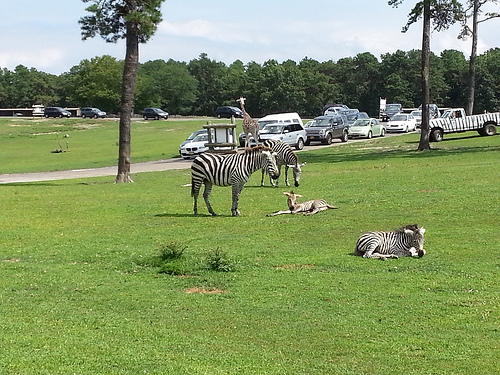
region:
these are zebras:
[51, 21, 336, 291]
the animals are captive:
[88, 113, 490, 360]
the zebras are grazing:
[170, 134, 377, 234]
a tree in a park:
[75, 0, 166, 184]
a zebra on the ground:
[352, 218, 427, 269]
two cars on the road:
[37, 101, 111, 121]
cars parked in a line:
[178, 98, 412, 156]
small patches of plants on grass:
[132, 231, 246, 289]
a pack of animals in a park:
[182, 135, 433, 270]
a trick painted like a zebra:
[427, 103, 498, 145]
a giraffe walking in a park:
[235, 87, 259, 149]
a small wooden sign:
[202, 115, 240, 153]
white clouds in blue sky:
[177, 1, 207, 36]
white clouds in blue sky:
[255, 19, 310, 44]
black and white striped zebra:
[182, 149, 273, 211]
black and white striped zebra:
[342, 215, 430, 257]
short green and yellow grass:
[261, 298, 293, 323]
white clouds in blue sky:
[0, 1, 67, 48]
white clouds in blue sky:
[260, 28, 335, 66]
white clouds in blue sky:
[285, 18, 355, 69]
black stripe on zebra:
[192, 176, 204, 183]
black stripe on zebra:
[190, 171, 205, 178]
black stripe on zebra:
[190, 162, 207, 177]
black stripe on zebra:
[193, 158, 211, 183]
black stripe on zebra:
[199, 151, 214, 181]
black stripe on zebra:
[204, 148, 218, 176]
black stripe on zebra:
[213, 153, 220, 162]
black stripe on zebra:
[359, 238, 378, 250]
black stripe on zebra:
[246, 150, 253, 175]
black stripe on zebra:
[248, 149, 256, 172]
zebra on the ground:
[348, 211, 444, 288]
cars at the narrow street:
[175, 102, 422, 154]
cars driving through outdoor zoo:
[4, 17, 491, 359]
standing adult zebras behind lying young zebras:
[180, 137, 430, 265]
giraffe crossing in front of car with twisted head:
[223, 92, 306, 146]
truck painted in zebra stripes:
[421, 99, 497, 146]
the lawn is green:
[366, 310, 428, 372]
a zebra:
[191, 145, 286, 208]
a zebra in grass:
[186, 147, 276, 219]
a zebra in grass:
[357, 225, 424, 260]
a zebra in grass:
[246, 135, 301, 190]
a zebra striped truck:
[424, 104, 496, 144]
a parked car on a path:
[184, 134, 229, 160]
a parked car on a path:
[253, 121, 305, 149]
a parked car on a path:
[303, 113, 353, 144]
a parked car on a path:
[346, 119, 383, 141]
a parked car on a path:
[388, 111, 414, 131]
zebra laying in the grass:
[356, 223, 451, 268]